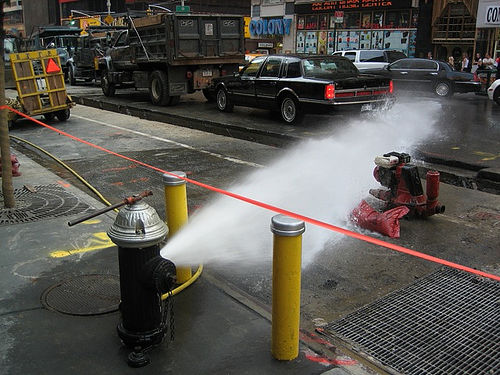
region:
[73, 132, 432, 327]
Water gushing from fire hydrant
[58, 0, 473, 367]
Busy street in a city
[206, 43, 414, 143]
Black car behind the truck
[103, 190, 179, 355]
Black and silver fire hydrant on the sidewalk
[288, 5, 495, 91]
Store on the right side of the road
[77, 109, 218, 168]
White lane making on the road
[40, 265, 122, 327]
Black manhole cover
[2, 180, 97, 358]
Grey sidewalk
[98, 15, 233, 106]
Black truck on the road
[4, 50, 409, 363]
Left lane closed for vehicles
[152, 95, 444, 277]
water spraying out onto the street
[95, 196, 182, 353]
black fire hydrant that has been opened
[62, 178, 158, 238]
a wrench to open the fire hydrant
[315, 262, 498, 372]
metal grate that leads below the street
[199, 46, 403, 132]
black car stopped in the street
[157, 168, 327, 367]
two yellow posts next to the fire hydrant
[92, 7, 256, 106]
a dirty dump truck in the road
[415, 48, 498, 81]
group of people walking along the road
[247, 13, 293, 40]
blue sign that says COLONY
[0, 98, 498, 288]
orange tape tied to a post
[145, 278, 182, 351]
metal chain attached to the side of the fire hydrant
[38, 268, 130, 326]
man hole cover on the sidewalk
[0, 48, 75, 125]
trailer parked on the road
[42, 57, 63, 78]
an orange warning sign on the trailer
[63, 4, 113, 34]
stop light by the road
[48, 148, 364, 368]
location markers on the road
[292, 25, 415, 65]
covered up window on the building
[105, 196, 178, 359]
black and silver fire hydrant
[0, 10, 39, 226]
tree next to the road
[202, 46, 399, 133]
black car in the middle of the road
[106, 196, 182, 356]
A silver and black fire hydrant.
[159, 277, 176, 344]
Black chains on a fire hydrant.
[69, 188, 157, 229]
A wrench.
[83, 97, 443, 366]
A fire hydrant spraying water into the street.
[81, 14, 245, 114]
A large dark colored dump truck.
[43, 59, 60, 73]
An orange caution triangle sign.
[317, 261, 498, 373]
A storm drain on the road.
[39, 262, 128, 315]
A round manhole on the sidewalk.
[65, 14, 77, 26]
A traffic light displaying a green light.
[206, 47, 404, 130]
A black 4-door car, with its taillights on.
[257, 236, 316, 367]
Yellow pole on the curb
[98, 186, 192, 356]
A black fire hydrant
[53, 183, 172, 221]
A fireman's wrench on the hydrant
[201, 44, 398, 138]
A black car in the road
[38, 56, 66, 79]
An orange triangular sign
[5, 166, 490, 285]
A line of red tape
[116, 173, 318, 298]
The hydrant is spraying water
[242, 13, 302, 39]
The sign says colony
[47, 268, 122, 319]
A manhole on the sidewalk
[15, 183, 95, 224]
Drainage holes near the road